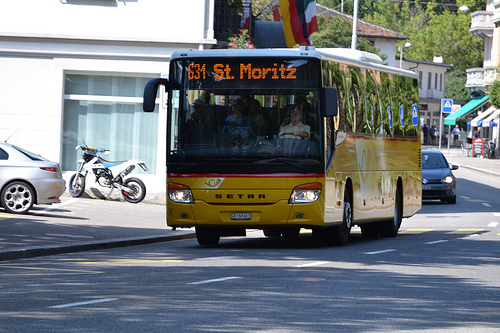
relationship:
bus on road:
[139, 40, 430, 251] [0, 147, 498, 332]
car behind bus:
[421, 145, 461, 209] [139, 40, 430, 251]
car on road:
[421, 145, 461, 209] [0, 147, 498, 332]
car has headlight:
[421, 145, 461, 209] [441, 173, 456, 188]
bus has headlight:
[139, 40, 430, 251] [282, 183, 322, 209]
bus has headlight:
[139, 40, 430, 251] [162, 182, 197, 211]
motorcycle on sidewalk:
[67, 137, 151, 206] [66, 177, 167, 211]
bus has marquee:
[139, 40, 430, 251] [165, 53, 326, 94]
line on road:
[41, 190, 500, 324] [0, 147, 498, 332]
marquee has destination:
[165, 53, 326, 94] [181, 60, 299, 85]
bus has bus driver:
[139, 40, 430, 251] [277, 104, 314, 144]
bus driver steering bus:
[277, 104, 314, 144] [139, 40, 430, 251]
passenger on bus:
[223, 98, 251, 126] [139, 40, 430, 251]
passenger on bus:
[244, 97, 268, 134] [139, 40, 430, 251]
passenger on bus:
[188, 96, 211, 128] [139, 40, 430, 251]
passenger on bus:
[289, 93, 315, 113] [139, 40, 430, 251]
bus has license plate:
[139, 40, 430, 251] [224, 207, 255, 224]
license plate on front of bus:
[224, 207, 255, 224] [139, 40, 430, 251]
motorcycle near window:
[67, 137, 151, 206] [54, 66, 164, 181]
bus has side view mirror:
[139, 40, 430, 251] [318, 82, 344, 124]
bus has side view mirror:
[139, 40, 430, 251] [136, 73, 169, 119]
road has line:
[0, 147, 498, 332] [41, 190, 500, 324]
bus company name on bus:
[209, 189, 269, 208] [139, 40, 430, 251]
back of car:
[15, 143, 70, 214] [0, 134, 69, 220]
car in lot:
[0, 134, 69, 220] [0, 190, 82, 225]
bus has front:
[139, 40, 430, 251] [138, 46, 359, 251]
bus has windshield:
[139, 40, 430, 251] [168, 87, 325, 175]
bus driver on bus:
[277, 104, 314, 144] [139, 40, 430, 251]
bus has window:
[139, 40, 430, 251] [336, 84, 369, 135]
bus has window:
[139, 40, 430, 251] [364, 89, 391, 139]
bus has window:
[139, 40, 430, 251] [398, 97, 421, 136]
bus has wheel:
[139, 40, 430, 251] [308, 175, 360, 249]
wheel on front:
[308, 175, 360, 249] [138, 46, 359, 251]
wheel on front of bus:
[308, 175, 360, 249] [139, 40, 430, 251]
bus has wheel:
[139, 40, 430, 251] [358, 172, 408, 245]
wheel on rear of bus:
[358, 172, 408, 245] [139, 40, 430, 251]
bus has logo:
[139, 40, 430, 251] [209, 189, 269, 208]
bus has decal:
[139, 40, 430, 251] [196, 174, 229, 192]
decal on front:
[196, 174, 229, 192] [138, 46, 359, 251]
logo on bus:
[210, 191, 272, 207] [139, 40, 430, 251]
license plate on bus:
[224, 207, 255, 224] [139, 40, 430, 251]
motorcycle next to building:
[67, 137, 151, 206] [1, 0, 256, 196]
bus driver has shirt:
[277, 104, 314, 144] [274, 121, 314, 143]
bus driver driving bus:
[277, 104, 314, 144] [139, 40, 430, 251]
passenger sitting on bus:
[223, 98, 251, 126] [139, 40, 430, 251]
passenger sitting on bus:
[188, 96, 211, 128] [139, 40, 430, 251]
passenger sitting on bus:
[289, 93, 315, 113] [139, 40, 430, 251]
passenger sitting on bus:
[244, 97, 268, 134] [139, 40, 430, 251]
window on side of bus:
[336, 84, 369, 135] [139, 40, 430, 251]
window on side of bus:
[364, 89, 391, 139] [139, 40, 430, 251]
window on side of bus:
[398, 97, 421, 136] [139, 40, 430, 251]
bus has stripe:
[139, 40, 430, 251] [165, 134, 424, 180]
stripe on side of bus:
[165, 134, 424, 180] [139, 40, 430, 251]